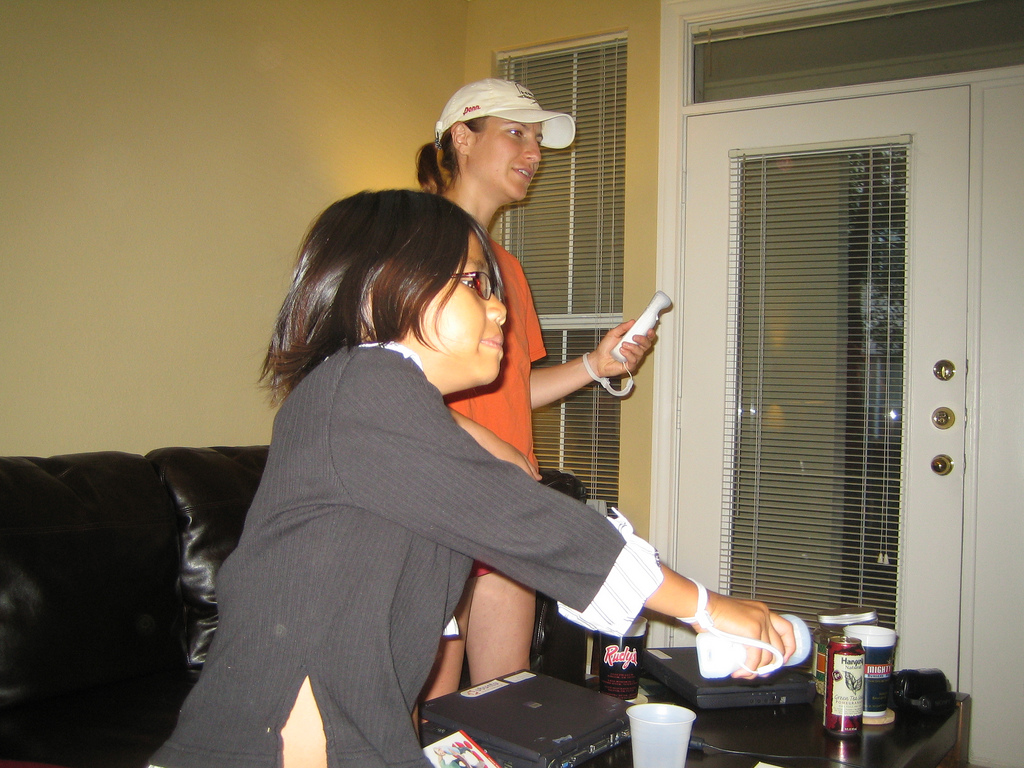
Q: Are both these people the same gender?
A: Yes, all the people are female.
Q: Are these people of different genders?
A: No, all the people are female.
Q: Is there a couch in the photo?
A: Yes, there is a couch.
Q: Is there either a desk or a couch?
A: Yes, there is a couch.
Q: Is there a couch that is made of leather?
A: Yes, there is a couch that is made of leather.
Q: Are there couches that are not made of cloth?
A: Yes, there is a couch that is made of leather.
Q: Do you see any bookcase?
A: No, there are no bookcases.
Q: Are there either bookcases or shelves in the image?
A: No, there are no bookcases or shelves.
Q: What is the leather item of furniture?
A: The piece of furniture is a couch.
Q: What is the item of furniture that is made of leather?
A: The piece of furniture is a couch.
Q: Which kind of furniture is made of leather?
A: The furniture is a couch.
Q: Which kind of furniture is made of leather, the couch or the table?
A: The couch is made of leather.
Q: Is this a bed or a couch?
A: This is a couch.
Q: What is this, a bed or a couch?
A: This is a couch.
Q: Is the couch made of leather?
A: Yes, the couch is made of leather.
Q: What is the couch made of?
A: The couch is made of leather.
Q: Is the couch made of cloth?
A: No, the couch is made of leather.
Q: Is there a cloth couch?
A: No, there is a couch but it is made of leather.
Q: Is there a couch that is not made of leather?
A: No, there is a couch but it is made of leather.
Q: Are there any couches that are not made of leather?
A: No, there is a couch but it is made of leather.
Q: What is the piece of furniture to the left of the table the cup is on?
A: The piece of furniture is a couch.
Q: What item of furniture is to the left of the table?
A: The piece of furniture is a couch.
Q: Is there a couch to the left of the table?
A: Yes, there is a couch to the left of the table.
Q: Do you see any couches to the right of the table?
A: No, the couch is to the left of the table.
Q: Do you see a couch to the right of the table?
A: No, the couch is to the left of the table.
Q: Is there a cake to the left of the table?
A: No, there is a couch to the left of the table.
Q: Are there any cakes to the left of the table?
A: No, there is a couch to the left of the table.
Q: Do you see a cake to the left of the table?
A: No, there is a couch to the left of the table.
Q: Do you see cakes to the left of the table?
A: No, there is a couch to the left of the table.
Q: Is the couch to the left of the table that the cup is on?
A: Yes, the couch is to the left of the table.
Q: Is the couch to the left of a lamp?
A: No, the couch is to the left of the table.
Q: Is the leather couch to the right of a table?
A: No, the couch is to the left of a table.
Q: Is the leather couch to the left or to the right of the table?
A: The couch is to the left of the table.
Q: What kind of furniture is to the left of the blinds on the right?
A: The piece of furniture is a couch.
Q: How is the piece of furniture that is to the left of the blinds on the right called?
A: The piece of furniture is a couch.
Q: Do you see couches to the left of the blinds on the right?
A: Yes, there is a couch to the left of the blinds.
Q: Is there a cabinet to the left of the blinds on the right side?
A: No, there is a couch to the left of the blinds.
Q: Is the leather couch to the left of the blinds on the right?
A: Yes, the couch is to the left of the blinds.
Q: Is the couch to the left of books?
A: No, the couch is to the left of the blinds.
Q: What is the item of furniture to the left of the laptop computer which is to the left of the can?
A: The piece of furniture is a couch.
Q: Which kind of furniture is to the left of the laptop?
A: The piece of furniture is a couch.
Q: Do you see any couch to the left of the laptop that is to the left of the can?
A: Yes, there is a couch to the left of the laptop.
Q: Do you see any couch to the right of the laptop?
A: No, the couch is to the left of the laptop.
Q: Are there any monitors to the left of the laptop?
A: No, there is a couch to the left of the laptop.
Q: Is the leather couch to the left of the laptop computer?
A: Yes, the couch is to the left of the laptop computer.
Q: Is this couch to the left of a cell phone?
A: No, the couch is to the left of the laptop computer.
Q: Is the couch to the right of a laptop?
A: No, the couch is to the left of a laptop.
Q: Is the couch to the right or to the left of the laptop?
A: The couch is to the left of the laptop.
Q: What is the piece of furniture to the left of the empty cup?
A: The piece of furniture is a couch.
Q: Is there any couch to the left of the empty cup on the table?
A: Yes, there is a couch to the left of the cup.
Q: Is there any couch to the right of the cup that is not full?
A: No, the couch is to the left of the cup.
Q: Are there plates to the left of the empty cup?
A: No, there is a couch to the left of the cup.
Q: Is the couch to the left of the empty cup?
A: Yes, the couch is to the left of the cup.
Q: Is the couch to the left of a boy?
A: No, the couch is to the left of the cup.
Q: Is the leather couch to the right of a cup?
A: No, the couch is to the left of a cup.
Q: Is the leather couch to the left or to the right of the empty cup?
A: The couch is to the left of the cup.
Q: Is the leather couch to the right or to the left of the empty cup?
A: The couch is to the left of the cup.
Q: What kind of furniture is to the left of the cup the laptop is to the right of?
A: The piece of furniture is a couch.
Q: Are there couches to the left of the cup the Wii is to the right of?
A: Yes, there is a couch to the left of the cup.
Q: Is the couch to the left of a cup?
A: Yes, the couch is to the left of a cup.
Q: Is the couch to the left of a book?
A: No, the couch is to the left of a cup.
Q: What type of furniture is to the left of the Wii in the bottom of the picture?
A: The piece of furniture is a couch.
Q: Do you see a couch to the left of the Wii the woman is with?
A: Yes, there is a couch to the left of the Wii.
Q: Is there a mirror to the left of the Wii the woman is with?
A: No, there is a couch to the left of the Wii.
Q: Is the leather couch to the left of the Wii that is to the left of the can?
A: Yes, the couch is to the left of the Wii.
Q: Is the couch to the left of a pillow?
A: No, the couch is to the left of the Wii.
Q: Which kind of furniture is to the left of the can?
A: The piece of furniture is a couch.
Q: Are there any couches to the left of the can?
A: Yes, there is a couch to the left of the can.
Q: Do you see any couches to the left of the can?
A: Yes, there is a couch to the left of the can.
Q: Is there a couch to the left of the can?
A: Yes, there is a couch to the left of the can.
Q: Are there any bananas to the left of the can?
A: No, there is a couch to the left of the can.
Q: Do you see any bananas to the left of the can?
A: No, there is a couch to the left of the can.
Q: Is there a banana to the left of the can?
A: No, there is a couch to the left of the can.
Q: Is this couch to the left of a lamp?
A: No, the couch is to the left of the can.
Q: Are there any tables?
A: Yes, there is a table.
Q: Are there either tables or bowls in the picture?
A: Yes, there is a table.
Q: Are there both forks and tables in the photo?
A: No, there is a table but no forks.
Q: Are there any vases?
A: No, there are no vases.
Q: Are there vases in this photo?
A: No, there are no vases.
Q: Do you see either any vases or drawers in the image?
A: No, there are no vases or drawers.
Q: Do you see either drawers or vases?
A: No, there are no vases or drawers.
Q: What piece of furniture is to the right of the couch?
A: The piece of furniture is a table.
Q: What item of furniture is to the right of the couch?
A: The piece of furniture is a table.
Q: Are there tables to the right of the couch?
A: Yes, there is a table to the right of the couch.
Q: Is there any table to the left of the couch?
A: No, the table is to the right of the couch.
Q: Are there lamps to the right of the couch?
A: No, there is a table to the right of the couch.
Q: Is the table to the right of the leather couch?
A: Yes, the table is to the right of the couch.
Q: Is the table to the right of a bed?
A: No, the table is to the right of the couch.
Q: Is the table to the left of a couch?
A: No, the table is to the right of a couch.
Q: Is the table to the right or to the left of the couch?
A: The table is to the right of the couch.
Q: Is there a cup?
A: Yes, there is a cup.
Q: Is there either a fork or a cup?
A: Yes, there is a cup.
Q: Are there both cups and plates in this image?
A: No, there is a cup but no plates.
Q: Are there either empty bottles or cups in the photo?
A: Yes, there is an empty cup.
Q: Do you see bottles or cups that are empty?
A: Yes, the cup is empty.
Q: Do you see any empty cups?
A: Yes, there is an empty cup.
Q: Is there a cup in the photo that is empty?
A: Yes, there is a cup that is empty.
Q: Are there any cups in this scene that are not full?
A: Yes, there is a empty cup.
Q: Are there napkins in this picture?
A: No, there are no napkins.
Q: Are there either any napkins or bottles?
A: No, there are no napkins or bottles.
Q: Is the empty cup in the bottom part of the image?
A: Yes, the cup is in the bottom of the image.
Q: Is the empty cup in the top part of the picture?
A: No, the cup is in the bottom of the image.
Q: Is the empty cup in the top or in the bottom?
A: The cup is in the bottom of the image.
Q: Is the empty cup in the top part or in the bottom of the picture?
A: The cup is in the bottom of the image.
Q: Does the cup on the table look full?
A: No, the cup is empty.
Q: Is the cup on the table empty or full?
A: The cup is empty.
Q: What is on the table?
A: The cup is on the table.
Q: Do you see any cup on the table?
A: Yes, there is a cup on the table.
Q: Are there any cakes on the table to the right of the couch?
A: No, there is a cup on the table.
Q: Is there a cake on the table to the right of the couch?
A: No, there is a cup on the table.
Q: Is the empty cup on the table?
A: Yes, the cup is on the table.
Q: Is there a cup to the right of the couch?
A: Yes, there is a cup to the right of the couch.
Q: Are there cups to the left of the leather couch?
A: No, the cup is to the right of the couch.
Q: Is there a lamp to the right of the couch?
A: No, there is a cup to the right of the couch.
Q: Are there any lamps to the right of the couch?
A: No, there is a cup to the right of the couch.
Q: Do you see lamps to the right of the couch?
A: No, there is a cup to the right of the couch.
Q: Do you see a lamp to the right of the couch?
A: No, there is a cup to the right of the couch.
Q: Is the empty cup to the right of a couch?
A: Yes, the cup is to the right of a couch.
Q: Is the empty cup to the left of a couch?
A: No, the cup is to the right of a couch.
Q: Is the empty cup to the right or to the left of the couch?
A: The cup is to the right of the couch.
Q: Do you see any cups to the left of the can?
A: Yes, there is a cup to the left of the can.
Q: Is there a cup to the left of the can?
A: Yes, there is a cup to the left of the can.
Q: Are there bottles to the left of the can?
A: No, there is a cup to the left of the can.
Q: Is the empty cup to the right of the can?
A: No, the cup is to the left of the can.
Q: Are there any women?
A: Yes, there is a woman.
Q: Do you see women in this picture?
A: Yes, there is a woman.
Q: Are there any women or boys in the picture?
A: Yes, there is a woman.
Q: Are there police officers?
A: No, there are no police officers.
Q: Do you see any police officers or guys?
A: No, there are no police officers or guys.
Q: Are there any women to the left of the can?
A: Yes, there is a woman to the left of the can.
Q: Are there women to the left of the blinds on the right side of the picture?
A: Yes, there is a woman to the left of the blinds.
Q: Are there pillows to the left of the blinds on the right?
A: No, there is a woman to the left of the blinds.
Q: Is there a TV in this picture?
A: No, there are no televisions.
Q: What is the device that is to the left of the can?
A: The device is a Wii.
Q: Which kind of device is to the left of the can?
A: The device is a Wii.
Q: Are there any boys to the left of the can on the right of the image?
A: No, there is a Wii to the left of the can.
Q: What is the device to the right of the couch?
A: The device is a Wii.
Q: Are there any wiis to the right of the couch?
A: Yes, there is a Wii to the right of the couch.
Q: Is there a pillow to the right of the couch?
A: No, there is a Wii to the right of the couch.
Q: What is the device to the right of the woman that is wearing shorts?
A: The device is a Wii.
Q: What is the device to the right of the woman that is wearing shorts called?
A: The device is a Wii.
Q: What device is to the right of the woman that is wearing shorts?
A: The device is a Wii.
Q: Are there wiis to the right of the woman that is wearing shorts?
A: Yes, there is a Wii to the right of the woman.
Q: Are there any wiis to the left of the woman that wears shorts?
A: No, the Wii is to the right of the woman.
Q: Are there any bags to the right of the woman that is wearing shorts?
A: No, there is a Wii to the right of the woman.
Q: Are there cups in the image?
A: Yes, there is a cup.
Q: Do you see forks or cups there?
A: Yes, there is a cup.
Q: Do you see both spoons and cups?
A: No, there is a cup but no spoons.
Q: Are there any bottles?
A: No, there are no bottles.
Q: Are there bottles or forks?
A: No, there are no bottles or forks.